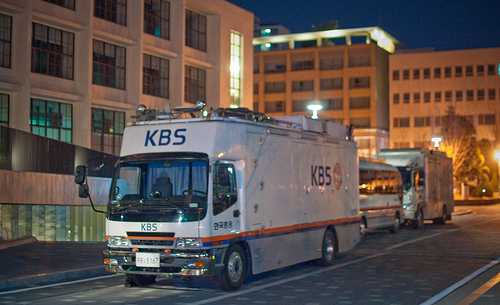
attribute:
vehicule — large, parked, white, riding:
[75, 104, 362, 292]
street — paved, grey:
[0, 202, 498, 304]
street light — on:
[305, 102, 324, 118]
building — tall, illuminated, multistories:
[2, 2, 255, 242]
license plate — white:
[136, 251, 162, 270]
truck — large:
[376, 146, 455, 229]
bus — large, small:
[359, 160, 405, 232]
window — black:
[32, 22, 76, 82]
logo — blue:
[312, 165, 333, 184]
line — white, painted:
[422, 254, 500, 303]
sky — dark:
[229, 1, 500, 50]